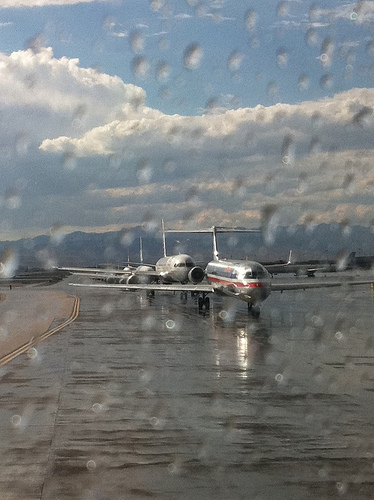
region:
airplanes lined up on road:
[30, 185, 368, 351]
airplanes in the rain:
[53, 209, 363, 385]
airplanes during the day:
[53, 213, 316, 377]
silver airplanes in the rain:
[73, 205, 362, 355]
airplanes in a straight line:
[89, 197, 356, 367]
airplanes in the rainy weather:
[75, 208, 371, 428]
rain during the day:
[23, 194, 342, 496]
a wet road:
[40, 307, 275, 498]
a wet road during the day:
[58, 309, 302, 475]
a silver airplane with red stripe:
[166, 202, 334, 367]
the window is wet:
[34, 288, 213, 448]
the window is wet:
[89, 271, 270, 430]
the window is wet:
[121, 300, 239, 496]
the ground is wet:
[24, 313, 196, 444]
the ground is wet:
[95, 342, 195, 458]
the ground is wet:
[86, 304, 230, 486]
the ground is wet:
[125, 355, 220, 494]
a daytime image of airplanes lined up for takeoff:
[0, 1, 372, 497]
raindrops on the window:
[181, 42, 201, 70]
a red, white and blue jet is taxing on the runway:
[69, 226, 369, 315]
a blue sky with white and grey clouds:
[0, 0, 372, 216]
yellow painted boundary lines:
[0, 288, 81, 368]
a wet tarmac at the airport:
[0, 368, 372, 498]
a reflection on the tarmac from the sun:
[230, 325, 257, 381]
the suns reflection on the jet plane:
[209, 261, 251, 286]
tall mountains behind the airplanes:
[0, 217, 372, 260]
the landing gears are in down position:
[197, 292, 210, 310]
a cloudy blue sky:
[25, 25, 331, 191]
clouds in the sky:
[33, 26, 228, 204]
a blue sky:
[115, 8, 321, 99]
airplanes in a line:
[80, 218, 342, 390]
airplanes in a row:
[80, 223, 283, 354]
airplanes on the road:
[72, 235, 372, 346]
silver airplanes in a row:
[61, 215, 288, 358]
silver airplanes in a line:
[82, 215, 302, 336]